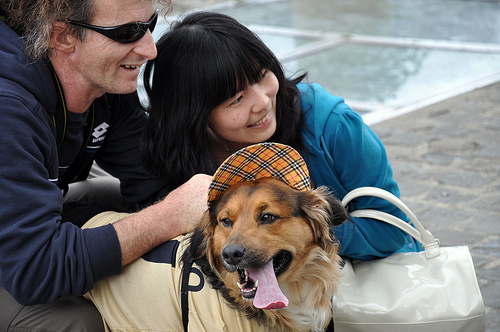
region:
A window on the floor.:
[321, 40, 498, 112]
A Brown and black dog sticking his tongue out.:
[208, 193, 327, 293]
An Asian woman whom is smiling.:
[158, 27, 297, 146]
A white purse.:
[332, 232, 487, 329]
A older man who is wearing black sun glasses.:
[5, 13, 170, 91]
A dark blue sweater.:
[0, 107, 142, 300]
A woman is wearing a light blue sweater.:
[291, 78, 431, 270]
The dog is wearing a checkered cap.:
[166, 154, 336, 284]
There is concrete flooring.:
[404, 110, 499, 221]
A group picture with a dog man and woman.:
[3, 20, 412, 281]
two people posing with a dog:
[0, 0, 411, 330]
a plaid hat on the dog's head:
[205, 143, 315, 213]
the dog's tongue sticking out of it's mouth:
[243, 255, 293, 312]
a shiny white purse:
[329, 181, 489, 330]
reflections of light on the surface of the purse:
[342, 261, 430, 316]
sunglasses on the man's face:
[56, 9, 162, 46]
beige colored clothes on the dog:
[68, 197, 268, 330]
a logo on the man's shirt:
[87, 117, 113, 151]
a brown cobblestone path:
[361, 77, 498, 330]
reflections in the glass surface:
[237, 3, 498, 110]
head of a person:
[143, 7, 302, 156]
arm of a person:
[68, 183, 188, 261]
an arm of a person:
[87, 186, 188, 288]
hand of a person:
[168, 178, 233, 232]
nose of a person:
[247, 90, 288, 118]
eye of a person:
[219, 79, 253, 117]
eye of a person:
[245, 60, 276, 90]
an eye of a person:
[227, 84, 257, 104]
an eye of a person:
[258, 55, 280, 82]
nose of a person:
[136, 39, 183, 61]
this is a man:
[2, 0, 223, 329]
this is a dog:
[74, 135, 349, 330]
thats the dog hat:
[202, 141, 314, 203]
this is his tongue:
[246, 259, 291, 320]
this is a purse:
[326, 185, 489, 330]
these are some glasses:
[52, 5, 164, 47]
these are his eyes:
[217, 209, 282, 229]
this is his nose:
[214, 243, 250, 262]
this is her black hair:
[142, 7, 314, 204]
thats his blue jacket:
[2, 26, 192, 313]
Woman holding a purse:
[315, 180, 494, 330]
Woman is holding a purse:
[324, 177, 495, 329]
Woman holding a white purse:
[317, 180, 489, 330]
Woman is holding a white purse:
[327, 184, 493, 330]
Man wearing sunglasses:
[49, 4, 169, 48]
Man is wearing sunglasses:
[50, 3, 166, 46]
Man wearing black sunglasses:
[45, 5, 162, 47]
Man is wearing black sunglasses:
[35, 7, 162, 46]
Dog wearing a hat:
[197, 136, 325, 233]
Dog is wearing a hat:
[200, 137, 325, 239]